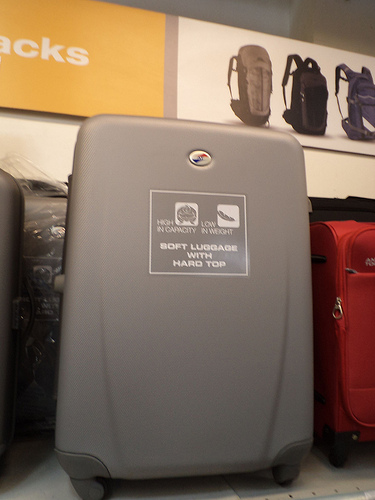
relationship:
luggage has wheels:
[47, 104, 323, 497] [323, 449, 354, 471]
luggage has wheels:
[311, 214, 375, 475] [323, 449, 354, 471]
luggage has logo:
[47, 104, 323, 497] [180, 144, 223, 171]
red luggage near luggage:
[311, 214, 375, 475] [47, 104, 323, 497]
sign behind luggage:
[3, 0, 172, 125] [47, 104, 323, 497]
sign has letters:
[3, 0, 172, 125] [3, 30, 101, 70]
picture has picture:
[176, 17, 374, 156] [221, 41, 372, 149]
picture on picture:
[221, 41, 372, 149] [176, 17, 374, 156]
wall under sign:
[2, 107, 374, 219] [3, 0, 172, 125]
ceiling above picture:
[111, 1, 373, 53] [176, 17, 374, 156]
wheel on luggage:
[73, 476, 116, 500] [47, 104, 323, 497]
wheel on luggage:
[269, 464, 302, 489] [47, 104, 323, 497]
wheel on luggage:
[323, 449, 354, 471] [311, 214, 375, 475]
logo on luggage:
[180, 144, 223, 171] [47, 104, 323, 497]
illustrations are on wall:
[212, 37, 279, 134] [1, 2, 374, 204]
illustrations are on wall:
[274, 48, 336, 140] [1, 2, 374, 204]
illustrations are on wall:
[332, 59, 375, 148] [1, 2, 374, 204]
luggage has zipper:
[311, 214, 375, 475] [328, 294, 347, 324]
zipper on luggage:
[328, 294, 347, 324] [311, 214, 375, 475]